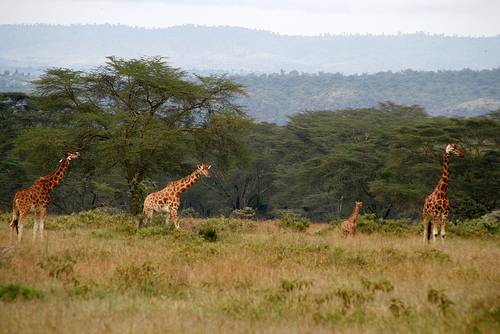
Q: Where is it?
A: This is at the field.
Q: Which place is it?
A: It is a field.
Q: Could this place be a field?
A: Yes, it is a field.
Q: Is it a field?
A: Yes, it is a field.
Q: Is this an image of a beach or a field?
A: It is showing a field.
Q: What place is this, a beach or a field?
A: It is a field.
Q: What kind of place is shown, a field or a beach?
A: It is a field.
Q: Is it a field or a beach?
A: It is a field.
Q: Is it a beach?
A: No, it is a field.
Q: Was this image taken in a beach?
A: No, the picture was taken in a field.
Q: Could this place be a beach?
A: No, it is a field.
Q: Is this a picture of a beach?
A: No, the picture is showing a field.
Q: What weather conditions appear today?
A: It is clear.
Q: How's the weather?
A: It is clear.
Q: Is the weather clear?
A: Yes, it is clear.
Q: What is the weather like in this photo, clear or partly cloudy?
A: It is clear.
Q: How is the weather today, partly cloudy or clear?
A: It is clear.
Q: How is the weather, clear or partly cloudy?
A: It is clear.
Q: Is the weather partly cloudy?
A: No, it is clear.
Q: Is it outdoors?
A: Yes, it is outdoors.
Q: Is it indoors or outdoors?
A: It is outdoors.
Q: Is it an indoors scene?
A: No, it is outdoors.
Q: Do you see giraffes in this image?
A: Yes, there is a giraffe.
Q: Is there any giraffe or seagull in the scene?
A: Yes, there is a giraffe.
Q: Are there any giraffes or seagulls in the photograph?
A: Yes, there is a giraffe.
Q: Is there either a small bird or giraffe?
A: Yes, there is a small giraffe.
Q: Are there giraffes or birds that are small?
A: Yes, the giraffe is small.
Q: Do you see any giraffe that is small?
A: Yes, there is a small giraffe.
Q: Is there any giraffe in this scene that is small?
A: Yes, there is a giraffe that is small.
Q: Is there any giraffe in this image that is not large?
A: Yes, there is a small giraffe.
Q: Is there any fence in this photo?
A: No, there are no fences.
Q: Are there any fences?
A: No, there are no fences.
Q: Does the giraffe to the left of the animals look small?
A: Yes, the giraffe is small.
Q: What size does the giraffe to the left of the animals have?
A: The giraffe has small size.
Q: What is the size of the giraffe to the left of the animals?
A: The giraffe is small.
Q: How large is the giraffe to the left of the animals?
A: The giraffe is small.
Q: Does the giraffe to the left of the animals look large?
A: No, the giraffe is small.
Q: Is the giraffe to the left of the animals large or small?
A: The giraffe is small.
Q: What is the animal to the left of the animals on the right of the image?
A: The animal is a giraffe.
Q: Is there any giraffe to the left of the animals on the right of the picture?
A: Yes, there is a giraffe to the left of the animals.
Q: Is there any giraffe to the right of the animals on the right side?
A: No, the giraffe is to the left of the animals.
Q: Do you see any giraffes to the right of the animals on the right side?
A: No, the giraffe is to the left of the animals.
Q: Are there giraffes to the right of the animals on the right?
A: No, the giraffe is to the left of the animals.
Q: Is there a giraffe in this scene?
A: Yes, there is a giraffe.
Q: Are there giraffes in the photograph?
A: Yes, there is a giraffe.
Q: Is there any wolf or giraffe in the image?
A: Yes, there is a giraffe.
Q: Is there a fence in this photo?
A: No, there are no fences.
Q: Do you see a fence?
A: No, there are no fences.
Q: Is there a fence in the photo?
A: No, there are no fences.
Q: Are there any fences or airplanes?
A: No, there are no fences or airplanes.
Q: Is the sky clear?
A: Yes, the sky is clear.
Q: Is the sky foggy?
A: No, the sky is clear.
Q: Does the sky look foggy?
A: No, the sky is clear.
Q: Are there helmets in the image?
A: No, there are no helmets.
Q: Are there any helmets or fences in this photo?
A: No, there are no helmets or fences.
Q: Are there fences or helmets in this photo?
A: No, there are no helmets or fences.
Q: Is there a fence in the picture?
A: No, there are no fences.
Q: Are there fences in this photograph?
A: No, there are no fences.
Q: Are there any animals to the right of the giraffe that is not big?
A: Yes, there are animals to the right of the giraffe.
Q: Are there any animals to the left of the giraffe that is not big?
A: No, the animals are to the right of the giraffe.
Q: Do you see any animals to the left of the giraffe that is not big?
A: No, the animals are to the right of the giraffe.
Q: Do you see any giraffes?
A: Yes, there is a giraffe.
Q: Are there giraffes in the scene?
A: Yes, there is a giraffe.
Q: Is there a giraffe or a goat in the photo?
A: Yes, there is a giraffe.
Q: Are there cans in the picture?
A: No, there are no cans.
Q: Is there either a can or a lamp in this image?
A: No, there are no cans or lamps.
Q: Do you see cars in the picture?
A: No, there are no cars.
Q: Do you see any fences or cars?
A: No, there are no cars or fences.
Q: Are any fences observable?
A: No, there are no fences.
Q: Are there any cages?
A: No, there are no cages.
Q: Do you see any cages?
A: No, there are no cages.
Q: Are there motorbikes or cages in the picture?
A: No, there are no cages or motorbikes.